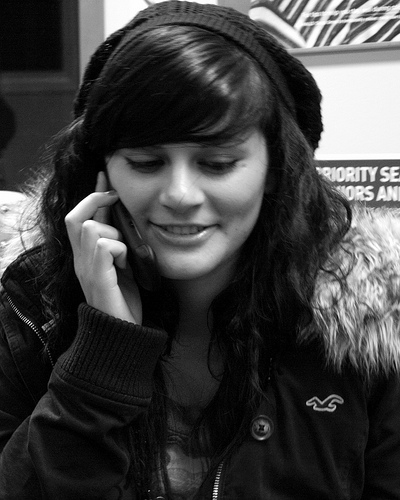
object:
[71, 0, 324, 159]
cap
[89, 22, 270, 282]
head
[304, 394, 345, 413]
seagull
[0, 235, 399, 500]
jacket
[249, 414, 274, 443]
button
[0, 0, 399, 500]
girl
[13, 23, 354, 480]
hair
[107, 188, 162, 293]
phone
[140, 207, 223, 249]
smile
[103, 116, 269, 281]
face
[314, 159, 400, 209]
sign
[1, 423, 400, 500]
down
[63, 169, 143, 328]
hand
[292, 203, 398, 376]
fur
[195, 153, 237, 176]
eye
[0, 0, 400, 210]
wall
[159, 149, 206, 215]
nose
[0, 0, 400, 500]
photograph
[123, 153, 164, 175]
eyes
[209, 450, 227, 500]
zipper